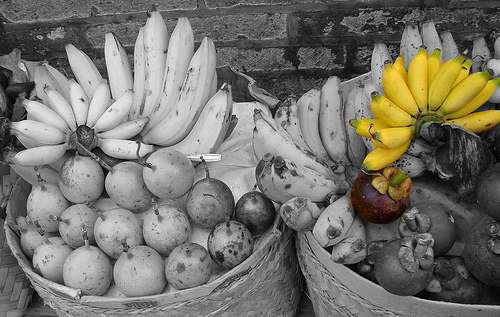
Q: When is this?
A: Daytime.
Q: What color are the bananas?
A: Yellow.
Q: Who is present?
A: No one.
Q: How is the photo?
A: Clear.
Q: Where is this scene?
A: Near bananas.